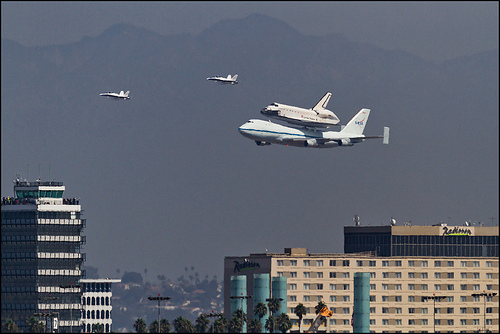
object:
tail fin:
[231, 73, 238, 81]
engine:
[304, 137, 319, 147]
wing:
[337, 107, 394, 145]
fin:
[340, 107, 371, 134]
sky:
[0, 0, 500, 281]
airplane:
[238, 108, 391, 149]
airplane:
[260, 91, 341, 128]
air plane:
[99, 90, 131, 101]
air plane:
[206, 74, 239, 85]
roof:
[343, 224, 498, 237]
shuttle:
[228, 92, 380, 155]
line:
[239, 124, 323, 140]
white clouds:
[20, 18, 112, 69]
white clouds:
[28, 94, 88, 134]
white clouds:
[123, 35, 211, 79]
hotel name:
[440, 225, 474, 236]